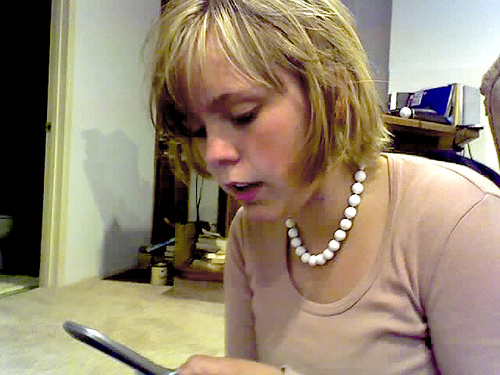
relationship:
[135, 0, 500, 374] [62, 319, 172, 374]
girl looking at cell phone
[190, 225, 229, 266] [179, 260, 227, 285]
books on shelf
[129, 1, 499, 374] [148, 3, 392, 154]
girl with hair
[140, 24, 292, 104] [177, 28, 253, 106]
baangs on forehead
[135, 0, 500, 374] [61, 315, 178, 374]
girl using phone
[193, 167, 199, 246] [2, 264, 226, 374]
wire onto floor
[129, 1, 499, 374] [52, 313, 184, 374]
girl on phone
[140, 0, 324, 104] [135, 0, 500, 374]
baangs of girl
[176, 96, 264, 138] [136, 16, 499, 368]
eyes of woman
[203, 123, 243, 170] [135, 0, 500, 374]
nose of girl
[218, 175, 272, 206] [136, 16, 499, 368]
mouth of woman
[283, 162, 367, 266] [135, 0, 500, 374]
necklace of girl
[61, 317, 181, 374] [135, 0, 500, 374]
cell phone of girl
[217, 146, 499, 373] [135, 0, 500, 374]
shirt of girl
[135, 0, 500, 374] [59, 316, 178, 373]
girl looking at cellphone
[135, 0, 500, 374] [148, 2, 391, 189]
girl with hair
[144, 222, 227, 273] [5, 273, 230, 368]
books on floor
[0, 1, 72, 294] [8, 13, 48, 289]
door way in bathroom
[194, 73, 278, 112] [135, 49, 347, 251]
eyebrow on face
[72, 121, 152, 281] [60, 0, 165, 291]
shadow on wall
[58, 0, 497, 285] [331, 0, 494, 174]
wall covered in paint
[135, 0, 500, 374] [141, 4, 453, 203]
girl has head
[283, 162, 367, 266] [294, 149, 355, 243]
necklace are on neck